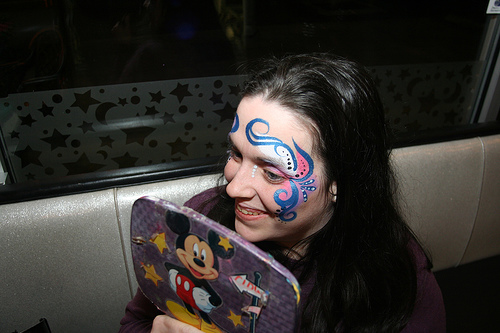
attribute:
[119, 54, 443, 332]
woman's — happy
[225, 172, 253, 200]
nose — woman's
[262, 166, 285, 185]
eye — green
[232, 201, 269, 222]
her mouth — pink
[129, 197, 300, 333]
mirror — purple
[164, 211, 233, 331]
mickey mouse art — mickey mouse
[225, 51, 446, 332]
woman — young, delighted, happy, smiling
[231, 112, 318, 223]
paint — colorful, blue, white, pink, swirly, beautiful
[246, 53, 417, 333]
hair — black, flowing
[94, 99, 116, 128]
moon — black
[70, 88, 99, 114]
star — black, cutout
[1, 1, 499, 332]
picture — clear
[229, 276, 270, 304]
arrow — white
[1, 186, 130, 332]
seat cushion — white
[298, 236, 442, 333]
shirt — purple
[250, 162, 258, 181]
dots — white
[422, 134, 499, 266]
cushions — white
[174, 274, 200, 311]
mickey's shorts — red